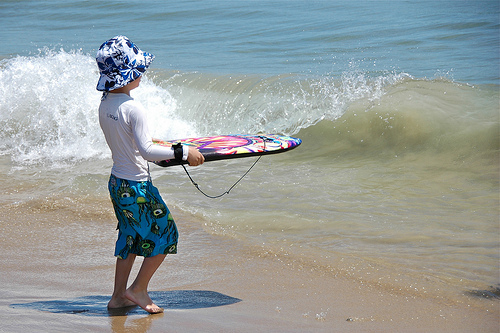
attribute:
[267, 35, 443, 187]
wave — small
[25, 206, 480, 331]
sand — wet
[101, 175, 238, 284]
short — blue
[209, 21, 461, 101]
water — blue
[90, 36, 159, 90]
hat — blue, white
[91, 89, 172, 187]
shirt — white, long sleeve